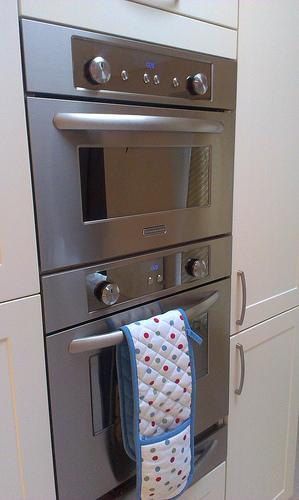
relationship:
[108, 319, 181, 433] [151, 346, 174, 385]
holde has polka dots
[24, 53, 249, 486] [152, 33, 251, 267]
stacked on each other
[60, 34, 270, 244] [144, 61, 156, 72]
stove has time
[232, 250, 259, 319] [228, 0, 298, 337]
handles on cupboard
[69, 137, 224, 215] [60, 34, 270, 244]
window on stove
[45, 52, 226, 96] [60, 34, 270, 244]
knobs on stove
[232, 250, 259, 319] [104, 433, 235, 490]
handles on bottom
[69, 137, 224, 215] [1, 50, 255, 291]
ovens on top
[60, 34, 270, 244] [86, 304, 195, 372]
oven mit hanging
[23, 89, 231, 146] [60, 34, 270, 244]
handles on oven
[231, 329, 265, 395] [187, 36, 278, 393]
handles to cupboard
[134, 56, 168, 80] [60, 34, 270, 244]
time on oven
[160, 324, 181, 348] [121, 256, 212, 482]
dots on mit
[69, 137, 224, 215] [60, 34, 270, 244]
window on oven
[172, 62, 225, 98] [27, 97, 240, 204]
dial on oven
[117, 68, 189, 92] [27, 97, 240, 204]
buttons on oven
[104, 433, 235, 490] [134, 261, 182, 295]
bottom oven buttons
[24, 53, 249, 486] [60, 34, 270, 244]
pair of ovens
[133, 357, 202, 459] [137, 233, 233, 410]
colorful oven towel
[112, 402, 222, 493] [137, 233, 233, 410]
pocket on towel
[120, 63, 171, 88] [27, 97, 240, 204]
display on oven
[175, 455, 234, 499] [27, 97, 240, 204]
drawer under oven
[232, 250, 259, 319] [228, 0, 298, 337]
handles to cupboard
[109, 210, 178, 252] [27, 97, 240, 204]
branding on oven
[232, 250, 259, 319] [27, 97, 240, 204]
handles of oven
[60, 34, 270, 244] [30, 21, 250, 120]
silver oven on top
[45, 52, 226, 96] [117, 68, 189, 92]
knobs and buttons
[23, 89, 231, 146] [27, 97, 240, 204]
handle on top door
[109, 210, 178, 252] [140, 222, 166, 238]
metal plate showing branding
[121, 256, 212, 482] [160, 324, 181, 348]
mitts covered in dots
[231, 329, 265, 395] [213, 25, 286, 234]
handles on cabinets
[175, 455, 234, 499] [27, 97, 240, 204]
drawer below oven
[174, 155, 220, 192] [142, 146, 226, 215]
reflection showing stripes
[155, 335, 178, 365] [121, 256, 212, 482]
quilted squares on mitts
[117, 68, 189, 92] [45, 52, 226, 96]
buttons between knobs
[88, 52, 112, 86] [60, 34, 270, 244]
knobs on cooker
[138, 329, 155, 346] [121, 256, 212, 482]
red doted holder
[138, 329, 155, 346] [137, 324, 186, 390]
red dot partten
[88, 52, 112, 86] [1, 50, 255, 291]
knobs on cooker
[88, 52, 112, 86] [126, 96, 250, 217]
knobs on cooker